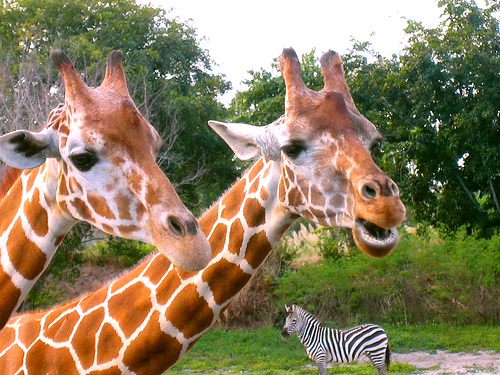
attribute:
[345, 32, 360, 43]
leaves — green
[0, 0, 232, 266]
tree — tall, green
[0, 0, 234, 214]
leaves — green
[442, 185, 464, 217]
leaves — green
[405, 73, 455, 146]
leaves — green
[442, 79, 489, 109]
leaves — green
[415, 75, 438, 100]
leaves — green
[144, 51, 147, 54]
leaf — green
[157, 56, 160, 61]
leaf — green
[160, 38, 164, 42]
leaf — green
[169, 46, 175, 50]
leaf — green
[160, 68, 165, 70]
leaf — green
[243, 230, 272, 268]
spot — brown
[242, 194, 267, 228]
spot — brown